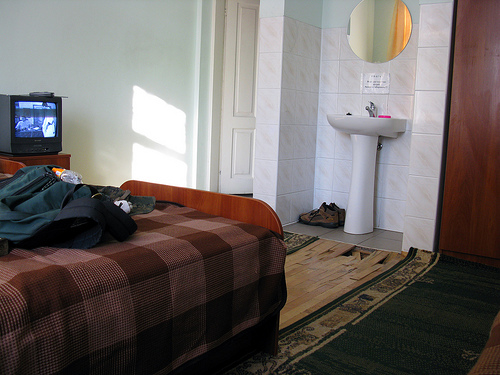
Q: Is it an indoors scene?
A: Yes, it is indoors.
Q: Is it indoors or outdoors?
A: It is indoors.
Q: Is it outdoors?
A: No, it is indoors.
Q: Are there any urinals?
A: No, there are no urinals.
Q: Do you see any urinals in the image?
A: No, there are no urinals.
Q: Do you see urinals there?
A: No, there are no urinals.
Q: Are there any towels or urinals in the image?
A: No, there are no urinals or towels.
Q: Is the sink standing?
A: Yes, the sink is standing.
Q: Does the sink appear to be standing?
A: Yes, the sink is standing.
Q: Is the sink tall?
A: Yes, the sink is tall.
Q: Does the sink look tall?
A: Yes, the sink is tall.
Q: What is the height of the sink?
A: The sink is tall.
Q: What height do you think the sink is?
A: The sink is tall.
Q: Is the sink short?
A: No, the sink is tall.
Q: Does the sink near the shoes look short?
A: No, the sink is tall.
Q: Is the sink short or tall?
A: The sink is tall.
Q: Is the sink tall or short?
A: The sink is tall.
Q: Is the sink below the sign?
A: Yes, the sink is below the sign.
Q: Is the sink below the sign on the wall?
A: Yes, the sink is below the sign.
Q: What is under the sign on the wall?
A: The sink is under the sign.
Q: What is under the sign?
A: The sink is under the sign.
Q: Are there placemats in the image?
A: No, there are no placemats.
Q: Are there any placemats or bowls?
A: No, there are no placemats or bowls.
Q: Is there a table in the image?
A: Yes, there is a table.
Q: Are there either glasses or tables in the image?
A: Yes, there is a table.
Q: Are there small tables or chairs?
A: Yes, there is a small table.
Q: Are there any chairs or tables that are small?
A: Yes, the table is small.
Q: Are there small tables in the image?
A: Yes, there is a small table.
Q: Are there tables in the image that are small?
A: Yes, there is a table that is small.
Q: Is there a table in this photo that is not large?
A: Yes, there is a small table.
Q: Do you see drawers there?
A: No, there are no drawers.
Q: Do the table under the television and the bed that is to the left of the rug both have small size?
A: Yes, both the table and the bed are small.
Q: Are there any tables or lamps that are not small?
A: No, there is a table but it is small.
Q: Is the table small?
A: Yes, the table is small.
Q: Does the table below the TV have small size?
A: Yes, the table is small.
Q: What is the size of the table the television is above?
A: The table is small.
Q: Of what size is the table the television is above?
A: The table is small.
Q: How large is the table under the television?
A: The table is small.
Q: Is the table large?
A: No, the table is small.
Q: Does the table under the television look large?
A: No, the table is small.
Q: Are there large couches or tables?
A: No, there is a table but it is small.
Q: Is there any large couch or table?
A: No, there is a table but it is small.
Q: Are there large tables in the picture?
A: No, there is a table but it is small.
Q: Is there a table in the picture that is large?
A: No, there is a table but it is small.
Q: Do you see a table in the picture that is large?
A: No, there is a table but it is small.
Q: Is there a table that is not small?
A: No, there is a table but it is small.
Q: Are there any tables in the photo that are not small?
A: No, there is a table but it is small.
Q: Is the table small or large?
A: The table is small.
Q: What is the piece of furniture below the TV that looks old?
A: The piece of furniture is a table.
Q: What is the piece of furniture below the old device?
A: The piece of furniture is a table.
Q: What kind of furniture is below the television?
A: The piece of furniture is a table.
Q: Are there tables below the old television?
A: Yes, there is a table below the TV.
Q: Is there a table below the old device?
A: Yes, there is a table below the TV.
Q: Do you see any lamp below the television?
A: No, there is a table below the television.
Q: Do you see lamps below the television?
A: No, there is a table below the television.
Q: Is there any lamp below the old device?
A: No, there is a table below the television.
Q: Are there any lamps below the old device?
A: No, there is a table below the television.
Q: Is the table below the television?
A: Yes, the table is below the television.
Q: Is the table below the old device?
A: Yes, the table is below the television.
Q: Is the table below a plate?
A: No, the table is below the television.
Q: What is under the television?
A: The table is under the television.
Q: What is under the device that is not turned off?
A: The table is under the television.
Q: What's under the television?
A: The table is under the television.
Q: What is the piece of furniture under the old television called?
A: The piece of furniture is a table.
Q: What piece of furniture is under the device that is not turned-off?
A: The piece of furniture is a table.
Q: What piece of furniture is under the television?
A: The piece of furniture is a table.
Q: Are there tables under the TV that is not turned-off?
A: Yes, there is a table under the TV.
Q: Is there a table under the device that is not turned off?
A: Yes, there is a table under the TV.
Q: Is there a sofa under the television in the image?
A: No, there is a table under the television.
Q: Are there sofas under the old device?
A: No, there is a table under the television.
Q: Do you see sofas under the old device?
A: No, there is a table under the television.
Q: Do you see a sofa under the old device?
A: No, there is a table under the television.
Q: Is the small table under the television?
A: Yes, the table is under the television.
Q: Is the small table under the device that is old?
A: Yes, the table is under the television.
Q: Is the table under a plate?
A: No, the table is under the television.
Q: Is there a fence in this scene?
A: No, there are no fences.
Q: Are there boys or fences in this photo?
A: No, there are no fences or boys.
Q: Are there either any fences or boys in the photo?
A: No, there are no fences or boys.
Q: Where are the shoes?
A: The shoes are on the floor.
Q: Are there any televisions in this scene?
A: Yes, there is a television.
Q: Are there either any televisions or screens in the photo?
A: Yes, there is a television.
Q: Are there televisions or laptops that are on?
A: Yes, the television is on.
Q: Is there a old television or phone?
A: Yes, there is an old television.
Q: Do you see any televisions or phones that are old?
A: Yes, the television is old.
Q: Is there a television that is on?
A: Yes, there is a television that is on.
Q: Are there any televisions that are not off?
A: Yes, there is a television that is on.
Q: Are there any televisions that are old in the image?
A: Yes, there is an old television.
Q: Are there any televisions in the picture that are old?
A: Yes, there is a television that is old.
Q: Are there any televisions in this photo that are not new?
A: Yes, there is a old television.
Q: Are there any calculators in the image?
A: No, there are no calculators.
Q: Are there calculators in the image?
A: No, there are no calculators.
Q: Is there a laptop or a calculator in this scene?
A: No, there are no calculators or laptops.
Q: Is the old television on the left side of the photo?
A: Yes, the television is on the left of the image.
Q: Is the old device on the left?
A: Yes, the television is on the left of the image.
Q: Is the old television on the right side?
A: No, the television is on the left of the image.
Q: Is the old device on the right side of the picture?
A: No, the television is on the left of the image.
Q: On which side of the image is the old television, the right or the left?
A: The TV is on the left of the image.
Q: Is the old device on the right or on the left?
A: The TV is on the left of the image.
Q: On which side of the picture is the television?
A: The television is on the left of the image.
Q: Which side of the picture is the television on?
A: The television is on the left of the image.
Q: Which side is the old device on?
A: The television is on the left of the image.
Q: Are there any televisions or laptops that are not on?
A: No, there is a television but it is on.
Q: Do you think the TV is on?
A: Yes, the TV is on.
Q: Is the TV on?
A: Yes, the TV is on.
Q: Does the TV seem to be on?
A: Yes, the TV is on.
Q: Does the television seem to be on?
A: Yes, the television is on.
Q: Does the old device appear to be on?
A: Yes, the television is on.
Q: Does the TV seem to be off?
A: No, the TV is on.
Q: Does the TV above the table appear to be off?
A: No, the television is on.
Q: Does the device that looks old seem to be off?
A: No, the television is on.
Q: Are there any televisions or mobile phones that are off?
A: No, there is a television but it is on.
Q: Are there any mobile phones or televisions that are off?
A: No, there is a television but it is on.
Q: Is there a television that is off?
A: No, there is a television but it is on.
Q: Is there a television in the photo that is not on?
A: No, there is a television but it is on.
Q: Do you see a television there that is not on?
A: No, there is a television but it is on.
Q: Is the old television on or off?
A: The television is on.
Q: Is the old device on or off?
A: The television is on.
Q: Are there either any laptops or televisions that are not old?
A: No, there is a television but it is old.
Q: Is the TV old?
A: Yes, the TV is old.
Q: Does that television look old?
A: Yes, the television is old.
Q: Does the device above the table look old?
A: Yes, the television is old.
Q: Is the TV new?
A: No, the TV is old.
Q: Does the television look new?
A: No, the television is old.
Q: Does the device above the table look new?
A: No, the television is old.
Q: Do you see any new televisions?
A: No, there is a television but it is old.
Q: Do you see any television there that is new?
A: No, there is a television but it is old.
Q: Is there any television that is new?
A: No, there is a television but it is old.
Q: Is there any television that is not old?
A: No, there is a television but it is old.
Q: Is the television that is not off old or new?
A: The TV is old.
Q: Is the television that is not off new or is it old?
A: The TV is old.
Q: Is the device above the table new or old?
A: The TV is old.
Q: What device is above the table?
A: The device is a television.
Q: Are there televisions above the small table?
A: Yes, there is a television above the table.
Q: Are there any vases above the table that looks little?
A: No, there is a television above the table.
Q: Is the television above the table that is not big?
A: Yes, the television is above the table.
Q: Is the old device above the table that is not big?
A: Yes, the television is above the table.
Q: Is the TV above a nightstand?
A: No, the TV is above the table.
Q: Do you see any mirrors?
A: Yes, there is a mirror.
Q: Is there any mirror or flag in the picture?
A: Yes, there is a mirror.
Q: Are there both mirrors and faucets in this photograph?
A: Yes, there are both a mirror and a faucet.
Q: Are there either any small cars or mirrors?
A: Yes, there is a small mirror.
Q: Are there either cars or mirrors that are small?
A: Yes, the mirror is small.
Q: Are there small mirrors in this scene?
A: Yes, there is a small mirror.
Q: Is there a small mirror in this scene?
A: Yes, there is a small mirror.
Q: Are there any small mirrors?
A: Yes, there is a small mirror.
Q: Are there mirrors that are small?
A: Yes, there is a mirror that is small.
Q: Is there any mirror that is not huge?
A: Yes, there is a small mirror.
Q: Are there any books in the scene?
A: No, there are no books.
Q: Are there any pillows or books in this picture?
A: No, there are no books or pillows.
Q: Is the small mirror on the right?
A: Yes, the mirror is on the right of the image.